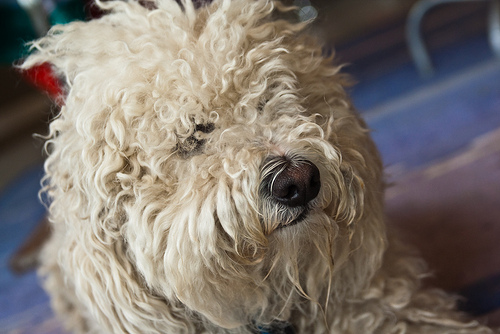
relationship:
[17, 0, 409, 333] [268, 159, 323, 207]
dog has nose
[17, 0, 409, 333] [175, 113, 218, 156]
dog has eye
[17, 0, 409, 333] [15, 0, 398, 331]
dog has head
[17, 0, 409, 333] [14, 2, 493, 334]
dog has fur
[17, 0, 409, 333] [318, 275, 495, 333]
dog has leg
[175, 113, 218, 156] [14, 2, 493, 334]
eye under fur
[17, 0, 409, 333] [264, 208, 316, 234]
dog has mouth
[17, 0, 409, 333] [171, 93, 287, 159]
dog has eyes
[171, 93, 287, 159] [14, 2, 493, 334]
eyes under fur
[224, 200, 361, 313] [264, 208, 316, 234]
fur around mouth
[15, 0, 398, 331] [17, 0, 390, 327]
head has fur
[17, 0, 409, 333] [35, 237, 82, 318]
dog has tail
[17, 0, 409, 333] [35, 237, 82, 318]
dog wagging tail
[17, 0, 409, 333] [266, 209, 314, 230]
dog has lips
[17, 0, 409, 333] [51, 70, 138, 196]
dog has ear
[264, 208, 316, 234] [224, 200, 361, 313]
mouth has fur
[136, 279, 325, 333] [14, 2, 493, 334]
collar under fur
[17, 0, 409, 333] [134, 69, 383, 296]
dog has face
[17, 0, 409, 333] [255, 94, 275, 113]
dog has eye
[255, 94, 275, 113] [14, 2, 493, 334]
eye under fur